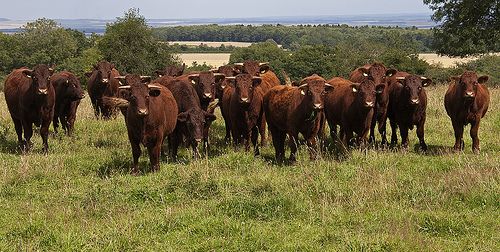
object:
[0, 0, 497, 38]
sky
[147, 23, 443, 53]
hills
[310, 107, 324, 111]
mouth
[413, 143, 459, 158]
shadow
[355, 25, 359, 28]
trees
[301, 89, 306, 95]
tag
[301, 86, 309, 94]
ear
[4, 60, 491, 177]
herd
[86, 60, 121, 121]
cows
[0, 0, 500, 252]
scene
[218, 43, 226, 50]
trees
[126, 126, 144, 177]
leg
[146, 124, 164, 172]
leg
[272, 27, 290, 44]
trees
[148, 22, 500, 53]
forest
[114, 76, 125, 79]
horns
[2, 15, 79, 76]
trees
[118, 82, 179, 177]
cow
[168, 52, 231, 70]
dried grass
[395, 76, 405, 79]
horns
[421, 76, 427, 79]
horns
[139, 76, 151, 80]
horns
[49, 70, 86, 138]
cows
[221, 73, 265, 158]
cattle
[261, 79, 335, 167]
cattle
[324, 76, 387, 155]
cattle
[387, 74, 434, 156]
cattle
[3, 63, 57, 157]
cows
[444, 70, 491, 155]
cow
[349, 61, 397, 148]
cow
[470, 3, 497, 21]
branches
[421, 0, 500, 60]
trees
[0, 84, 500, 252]
grass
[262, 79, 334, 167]
cow leaf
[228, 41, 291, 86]
trees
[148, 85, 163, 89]
horn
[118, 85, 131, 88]
horn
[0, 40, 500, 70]
field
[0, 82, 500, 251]
sun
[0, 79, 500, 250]
field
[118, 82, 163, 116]
head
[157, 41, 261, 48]
dirt